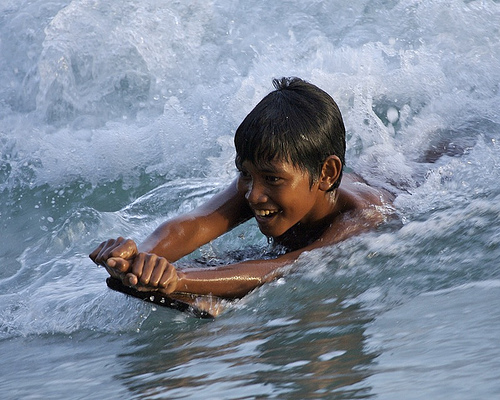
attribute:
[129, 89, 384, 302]
boy — wet, holding, smiling, surfing, happy, water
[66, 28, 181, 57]
water — rough, thick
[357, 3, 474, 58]
ocean — frothy, white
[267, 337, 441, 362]
wave — crashing, white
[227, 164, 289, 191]
eyes — open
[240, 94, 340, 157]
hair — short, wet, dark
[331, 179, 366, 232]
skin — wet, brown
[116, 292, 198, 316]
surfboard — black, wood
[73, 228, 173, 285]
fists — closed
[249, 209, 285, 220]
mouth — open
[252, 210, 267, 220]
teeth — white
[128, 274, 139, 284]
thumbnail — short